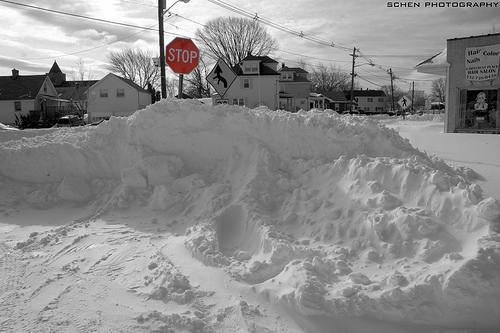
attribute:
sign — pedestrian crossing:
[398, 94, 413, 114]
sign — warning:
[202, 53, 241, 108]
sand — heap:
[208, 119, 499, 307]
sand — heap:
[9, 88, 497, 327]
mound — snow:
[11, 88, 484, 301]